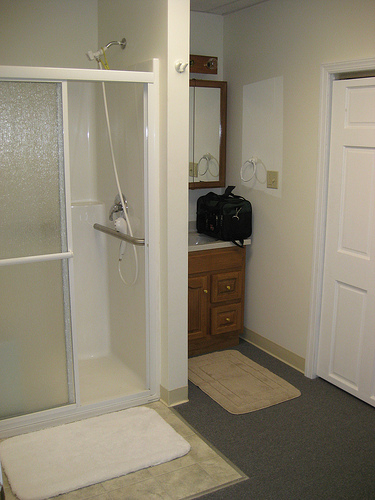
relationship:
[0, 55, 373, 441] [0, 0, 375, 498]
frame around bathroom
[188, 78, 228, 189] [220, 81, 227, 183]
mirror with border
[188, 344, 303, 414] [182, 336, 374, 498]
mat on carpet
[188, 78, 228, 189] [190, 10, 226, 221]
mirror on wall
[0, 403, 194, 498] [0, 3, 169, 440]
bath mat in front of shower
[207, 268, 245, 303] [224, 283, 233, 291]
drawer with knob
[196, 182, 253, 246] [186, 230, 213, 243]
black bag by sink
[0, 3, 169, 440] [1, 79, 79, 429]
shower has sliding door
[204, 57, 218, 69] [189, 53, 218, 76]
light bulb in fixture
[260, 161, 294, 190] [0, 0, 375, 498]
switch for bathroom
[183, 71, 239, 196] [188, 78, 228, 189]
cabinet with front mirror